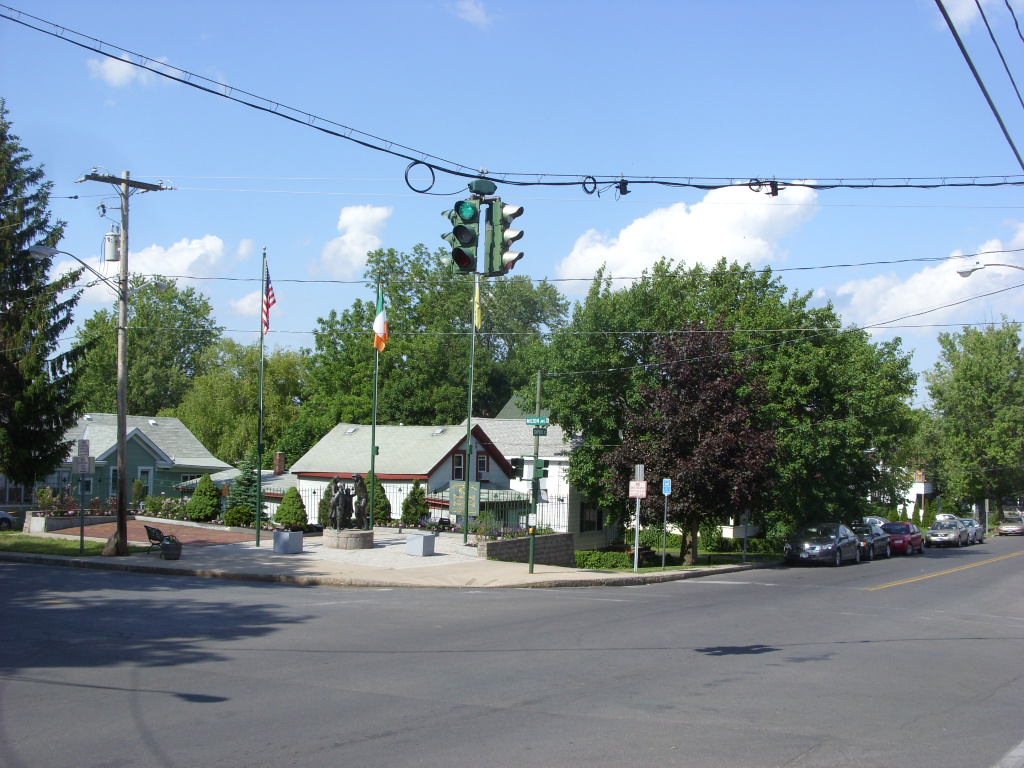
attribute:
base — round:
[322, 528, 374, 549]